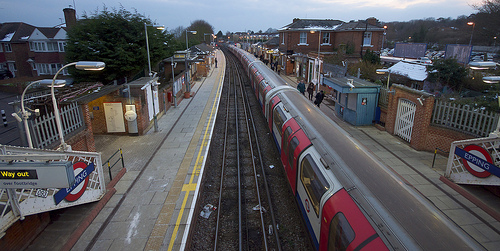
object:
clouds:
[247, 7, 332, 23]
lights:
[466, 21, 476, 45]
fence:
[431, 99, 500, 137]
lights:
[50, 61, 105, 144]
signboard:
[0, 169, 37, 179]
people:
[254, 54, 282, 75]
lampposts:
[20, 79, 67, 149]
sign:
[444, 136, 499, 186]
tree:
[62, 1, 175, 86]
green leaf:
[163, 34, 173, 44]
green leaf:
[123, 34, 135, 44]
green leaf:
[110, 27, 120, 39]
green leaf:
[130, 60, 140, 71]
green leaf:
[76, 32, 83, 43]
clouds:
[306, 0, 465, 15]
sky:
[0, 0, 499, 41]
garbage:
[199, 203, 216, 219]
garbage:
[269, 224, 280, 235]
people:
[296, 80, 328, 109]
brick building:
[0, 8, 77, 79]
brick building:
[276, 16, 385, 57]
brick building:
[60, 76, 171, 134]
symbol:
[51, 160, 94, 206]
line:
[166, 50, 225, 251]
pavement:
[0, 43, 499, 250]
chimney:
[62, 8, 78, 31]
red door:
[284, 128, 313, 197]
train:
[226, 44, 485, 251]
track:
[182, 46, 317, 250]